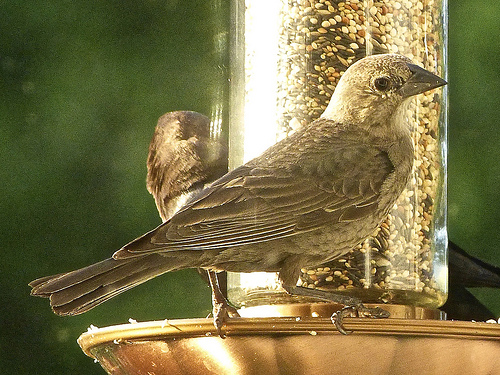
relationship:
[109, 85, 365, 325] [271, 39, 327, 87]
birds on bird feeder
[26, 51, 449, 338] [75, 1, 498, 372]
bird standing on feeder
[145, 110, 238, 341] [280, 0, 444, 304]
birds eating seeds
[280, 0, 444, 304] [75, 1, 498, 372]
seeds inside of feeder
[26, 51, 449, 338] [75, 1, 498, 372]
bird eating feeder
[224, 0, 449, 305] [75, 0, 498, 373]
glass top of bird feeder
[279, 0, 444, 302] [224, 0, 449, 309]
bird seed in glass feeder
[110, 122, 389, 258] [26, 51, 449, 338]
wing of bird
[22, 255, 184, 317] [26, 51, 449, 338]
tail of bird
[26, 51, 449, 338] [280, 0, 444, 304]
bird standing next to seeds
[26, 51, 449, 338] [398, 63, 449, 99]
bird has beak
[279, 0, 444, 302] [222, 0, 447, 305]
bird seed in glass tube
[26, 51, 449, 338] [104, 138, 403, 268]
bird has wing